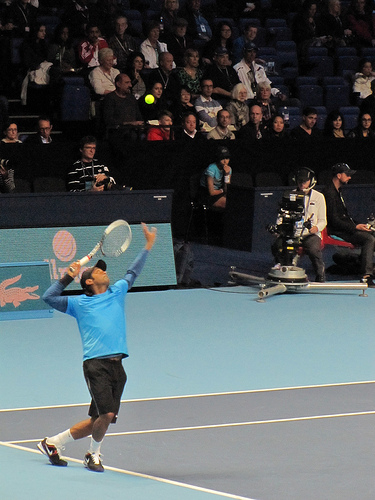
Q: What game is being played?
A: Tennis.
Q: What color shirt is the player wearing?
A: Blue.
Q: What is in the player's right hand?
A: Tennis racket.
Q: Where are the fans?
A: Stands.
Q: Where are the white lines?
A: Court.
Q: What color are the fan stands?
A: Black.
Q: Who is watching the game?
A: Spectators.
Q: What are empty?
A: Seats.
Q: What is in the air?
A: Tennis ball.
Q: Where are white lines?
A: On the court.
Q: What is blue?
A: Player's shirt.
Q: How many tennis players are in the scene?
A: One.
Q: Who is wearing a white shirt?
A: Cameraman.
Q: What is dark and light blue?
A: The tennis court.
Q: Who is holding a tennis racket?
A: A man.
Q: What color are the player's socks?
A: White.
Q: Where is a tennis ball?
A: In the air.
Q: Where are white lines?
A: On the court.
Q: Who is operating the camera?
A: A man in headsets.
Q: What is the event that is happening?
A: Tennis match.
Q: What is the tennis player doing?
A: Serving the ball.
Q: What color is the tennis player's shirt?
A: Blue.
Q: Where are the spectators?
A: In the stands.